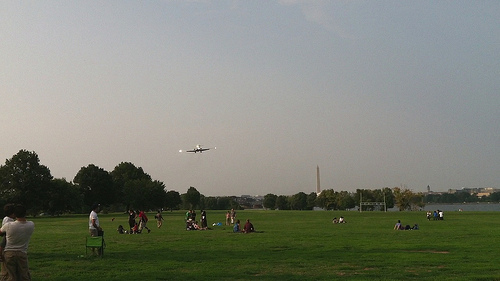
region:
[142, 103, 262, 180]
Plane in the air.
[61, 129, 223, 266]
Trees on the grass.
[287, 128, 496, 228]
Buildings in the background.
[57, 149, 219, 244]
Green trees.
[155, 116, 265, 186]
White plane in the sky.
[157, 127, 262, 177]
Wings on the plane.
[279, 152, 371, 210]
Tower in the background.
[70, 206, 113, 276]
Man with a green chair.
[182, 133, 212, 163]
white plane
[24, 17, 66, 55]
white clouds in blue sky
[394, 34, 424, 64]
white clouds in blue sky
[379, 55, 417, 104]
white clouds in blue sky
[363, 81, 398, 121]
white clouds in blue sky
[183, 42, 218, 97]
white clouds in blue sky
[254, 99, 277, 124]
white clouds in blue sky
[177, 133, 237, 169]
plane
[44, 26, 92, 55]
white clouds in blue sky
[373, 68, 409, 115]
white clouds in blue sky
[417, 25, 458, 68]
white clouds in blue sky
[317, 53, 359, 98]
white clouds in blue sky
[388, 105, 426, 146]
white clouds in blue sky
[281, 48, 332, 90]
white clouds in blue sky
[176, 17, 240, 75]
white clouds in blue sky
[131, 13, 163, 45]
white clouds in blue sky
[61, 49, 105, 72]
white clouds in blue sky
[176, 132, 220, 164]
the plane taking off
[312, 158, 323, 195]
the obelsk behind the trees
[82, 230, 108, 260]
the chair in the grass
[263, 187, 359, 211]
the line of trees across the field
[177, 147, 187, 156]
the sun shine glaring off the wings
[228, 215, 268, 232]
people sitting in the field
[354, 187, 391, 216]
the goal post on the field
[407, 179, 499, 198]
the buildings behind the tree line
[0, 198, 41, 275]
the women holding the child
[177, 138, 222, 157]
plane in an overcast sky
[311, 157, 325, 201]
skyscraper in the background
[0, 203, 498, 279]
large grassy field with people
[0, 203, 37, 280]
man holding a child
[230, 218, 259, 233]
couple sitting in grass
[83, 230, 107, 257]
green canvas chair by man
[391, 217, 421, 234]
couple laying on grass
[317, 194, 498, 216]
body of water beside field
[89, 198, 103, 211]
black baseball cap on man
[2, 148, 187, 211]
line of green trees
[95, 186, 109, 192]
green leaves on the tree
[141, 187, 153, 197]
green leaves on the tree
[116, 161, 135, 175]
green leaves on the tree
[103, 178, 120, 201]
green leaves on the tree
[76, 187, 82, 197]
green leaves on the tree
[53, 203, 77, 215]
green leaves on the tree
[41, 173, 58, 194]
green leaves on the tree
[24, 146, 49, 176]
green leaves on the tree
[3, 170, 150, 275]
green leaves on the tree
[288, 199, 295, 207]
green leaves on the tree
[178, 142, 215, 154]
white plane in sky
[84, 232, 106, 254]
green chair on lawn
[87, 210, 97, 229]
white shirt on man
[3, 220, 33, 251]
white shirt on person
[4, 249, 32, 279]
khaki shorts on person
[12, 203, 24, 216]
dark hair on person